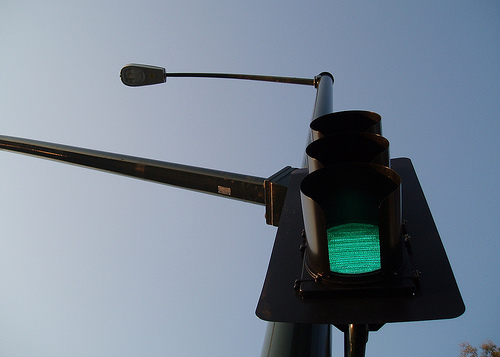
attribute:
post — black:
[300, 60, 335, 162]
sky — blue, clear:
[3, 2, 498, 355]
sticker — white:
[213, 182, 233, 195]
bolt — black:
[284, 274, 314, 303]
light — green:
[324, 217, 386, 277]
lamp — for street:
[95, 42, 188, 111]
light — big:
[268, 120, 472, 355]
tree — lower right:
[442, 326, 494, 355]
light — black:
[266, 116, 456, 328]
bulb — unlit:
[120, 65, 161, 85]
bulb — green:
[325, 206, 390, 276]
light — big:
[120, 62, 166, 86]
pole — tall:
[255, 72, 339, 348]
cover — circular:
[301, 165, 415, 212]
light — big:
[243, 93, 473, 354]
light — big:
[114, 58, 170, 90]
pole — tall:
[263, 54, 343, 354]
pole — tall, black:
[258, 63, 352, 354]